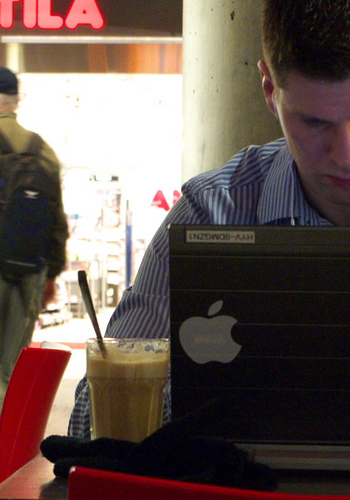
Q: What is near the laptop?
A: Glass.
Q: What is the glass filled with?
A: Substance.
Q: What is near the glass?
A: Gloves.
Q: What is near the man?
A: Chair.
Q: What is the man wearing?
A: Backpack.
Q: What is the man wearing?
A: Backpack.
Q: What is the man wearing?
A: Logo.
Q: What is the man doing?
A: Working.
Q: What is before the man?
A: Glass.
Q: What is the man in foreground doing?
A: Working on laptop.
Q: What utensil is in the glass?
A: Spoon.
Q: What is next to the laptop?
A: Glass.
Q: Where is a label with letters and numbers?
A: Laptop.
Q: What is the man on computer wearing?
A: Blue and white long sleeve shirt.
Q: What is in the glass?
A: Iced coffee.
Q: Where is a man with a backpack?
A: Near doorway.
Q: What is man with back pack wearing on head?
A: Black hat.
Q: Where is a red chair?
A: Next to the man at computer.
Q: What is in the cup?
A: A coffee beverage.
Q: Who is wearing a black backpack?
A: A man standing near the back f another man.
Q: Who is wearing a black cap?
A: A man standing with a black backpack.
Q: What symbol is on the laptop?
A: Apple logo.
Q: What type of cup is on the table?
A: Glass cup.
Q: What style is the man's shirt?
A: Long sleeves and stripes.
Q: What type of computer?
A: A laptop.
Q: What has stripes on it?
A: Shirt.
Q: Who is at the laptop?
A: A man.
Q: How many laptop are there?
A: One.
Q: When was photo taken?
A: Daytime.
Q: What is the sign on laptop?
A: Apple.